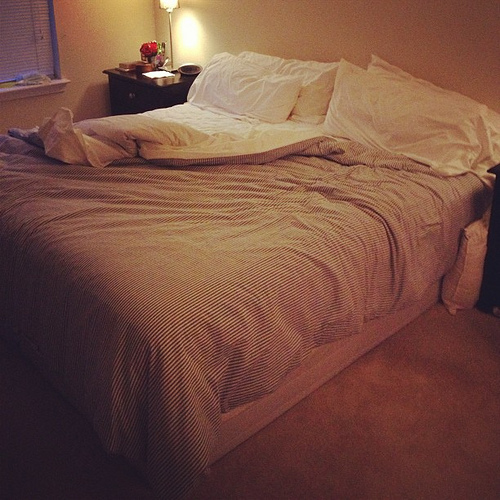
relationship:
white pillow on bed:
[320, 57, 495, 185] [1, 103, 487, 480]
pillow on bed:
[185, 53, 305, 125] [1, 103, 487, 480]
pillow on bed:
[235, 47, 335, 123] [1, 103, 487, 480]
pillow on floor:
[438, 201, 491, 313] [205, 300, 499, 498]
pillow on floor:
[438, 201, 491, 313] [0, 294, 500, 498]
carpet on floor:
[384, 350, 490, 490] [402, 318, 494, 495]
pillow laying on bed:
[185, 53, 305, 125] [4, 46, 495, 478]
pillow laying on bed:
[312, 57, 497, 182] [4, 46, 495, 478]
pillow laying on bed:
[364, 52, 498, 165] [4, 46, 495, 478]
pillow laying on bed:
[235, 47, 335, 123] [4, 46, 495, 478]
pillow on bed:
[312, 57, 497, 182] [4, 46, 495, 478]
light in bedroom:
[151, 0, 202, 62] [10, 20, 486, 498]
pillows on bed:
[210, 33, 381, 167] [4, 46, 495, 478]